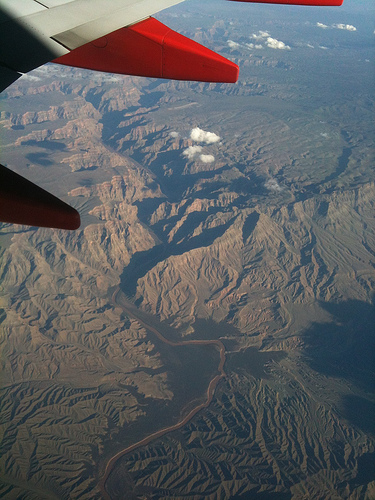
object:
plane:
[0, 3, 342, 230]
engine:
[60, 19, 239, 85]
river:
[95, 283, 229, 499]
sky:
[0, 1, 374, 499]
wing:
[2, 4, 178, 91]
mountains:
[2, 1, 375, 500]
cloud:
[184, 123, 223, 166]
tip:
[197, 46, 238, 84]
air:
[2, 3, 375, 499]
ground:
[0, 3, 374, 499]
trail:
[91, 187, 228, 500]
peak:
[110, 203, 134, 239]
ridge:
[135, 254, 180, 293]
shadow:
[303, 295, 374, 484]